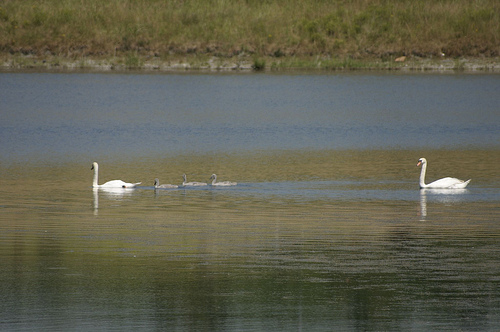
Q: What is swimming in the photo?
A: Ducks.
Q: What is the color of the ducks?
A: White.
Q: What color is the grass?
A: Green.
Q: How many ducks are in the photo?
A: Five.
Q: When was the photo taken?
A: Daytime.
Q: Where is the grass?
A: On the bank.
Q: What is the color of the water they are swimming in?
A: Green.